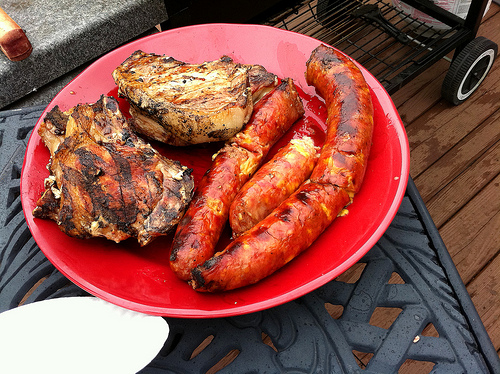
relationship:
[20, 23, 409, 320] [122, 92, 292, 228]
plate with food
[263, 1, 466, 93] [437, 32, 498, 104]
basket near wheel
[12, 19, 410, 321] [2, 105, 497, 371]
plate on table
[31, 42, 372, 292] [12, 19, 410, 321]
food on plate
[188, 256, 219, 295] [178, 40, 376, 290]
mark on sausage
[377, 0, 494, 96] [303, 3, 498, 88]
propane tank attached to grill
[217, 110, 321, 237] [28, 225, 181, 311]
sausage on plate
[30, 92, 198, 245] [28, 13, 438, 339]
meat on plate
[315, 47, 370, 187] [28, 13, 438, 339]
sausage on plate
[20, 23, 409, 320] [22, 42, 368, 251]
plate with food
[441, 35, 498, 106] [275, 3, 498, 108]
grill tire on a cart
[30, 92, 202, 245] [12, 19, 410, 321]
meat on plate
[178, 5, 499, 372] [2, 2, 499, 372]
floor in photo